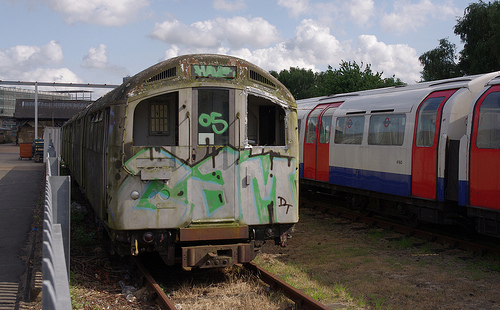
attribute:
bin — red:
[16, 137, 41, 159]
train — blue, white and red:
[95, 50, 352, 295]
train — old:
[61, 67, 301, 259]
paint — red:
[412, 92, 441, 195]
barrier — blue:
[29, 193, 101, 295]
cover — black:
[16, 97, 91, 117]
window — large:
[366, 112, 406, 147]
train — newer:
[289, 82, 496, 249]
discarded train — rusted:
[57, 54, 299, 274]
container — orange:
[18, 140, 35, 160]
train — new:
[309, 75, 499, 206]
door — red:
[410, 87, 440, 189]